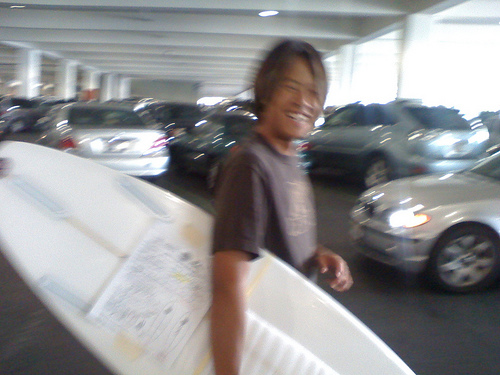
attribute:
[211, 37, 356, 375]
surfer — smiling, walking, blurry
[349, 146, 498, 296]
car — driving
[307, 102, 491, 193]
car — parked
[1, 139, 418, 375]
surfboard — white, new, long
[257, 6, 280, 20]
light — overhead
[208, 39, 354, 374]
man — walking, smiling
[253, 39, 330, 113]
hair — long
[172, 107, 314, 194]
vehicle — parked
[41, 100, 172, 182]
vehicle — parked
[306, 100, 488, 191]
vehicle — parked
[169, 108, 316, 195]
car — green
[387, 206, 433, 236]
headlight — lit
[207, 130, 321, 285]
shirt — brown